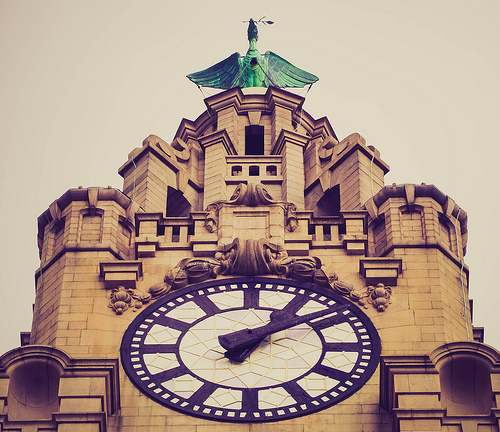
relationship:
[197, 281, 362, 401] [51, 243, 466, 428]
clock on wall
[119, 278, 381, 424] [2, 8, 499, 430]
clock on building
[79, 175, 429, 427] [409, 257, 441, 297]
building made of stone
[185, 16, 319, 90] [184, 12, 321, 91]
statue of bird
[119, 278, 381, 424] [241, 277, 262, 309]
clock has stripe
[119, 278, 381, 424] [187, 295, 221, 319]
clock has stripe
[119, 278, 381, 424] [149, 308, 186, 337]
clock has stripe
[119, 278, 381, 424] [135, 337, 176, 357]
clock has stripe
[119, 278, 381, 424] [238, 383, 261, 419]
clock has stripe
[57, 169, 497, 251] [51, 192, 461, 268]
railings on balcony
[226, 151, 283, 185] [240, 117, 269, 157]
railing in front of doorway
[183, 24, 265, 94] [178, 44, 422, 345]
statue on top of tower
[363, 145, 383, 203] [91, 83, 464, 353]
pipe on side of tower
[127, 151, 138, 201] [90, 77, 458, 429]
pipe on side of tower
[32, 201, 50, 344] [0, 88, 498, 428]
pipe on side of building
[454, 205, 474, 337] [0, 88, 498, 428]
pipe on side of building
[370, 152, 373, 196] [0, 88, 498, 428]
pipe on side of building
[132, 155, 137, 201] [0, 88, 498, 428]
pipe on side of building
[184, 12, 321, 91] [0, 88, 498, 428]
bird on top of of building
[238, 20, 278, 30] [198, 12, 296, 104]
rose in mouth of bird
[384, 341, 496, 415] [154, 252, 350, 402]
arch on side of clock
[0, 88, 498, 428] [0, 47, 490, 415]
building on tower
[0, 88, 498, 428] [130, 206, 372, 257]
building has a balcony